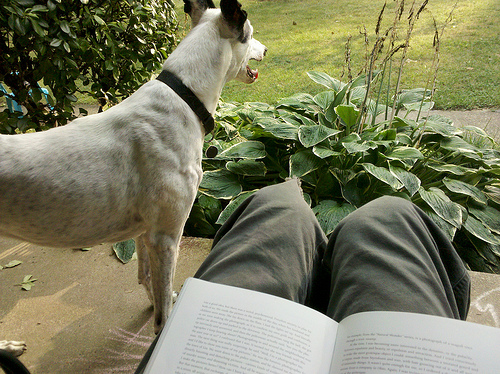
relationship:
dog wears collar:
[0, 0, 273, 325] [154, 71, 223, 131]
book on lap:
[133, 270, 497, 371] [195, 180, 455, 304]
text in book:
[204, 307, 309, 359] [133, 270, 497, 371]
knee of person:
[245, 169, 307, 220] [132, 176, 469, 373]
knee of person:
[341, 190, 427, 238] [132, 176, 469, 373]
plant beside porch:
[288, 88, 488, 231] [467, 264, 498, 322]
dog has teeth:
[0, 0, 273, 325] [248, 65, 261, 73]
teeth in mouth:
[248, 65, 261, 73] [242, 71, 262, 80]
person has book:
[132, 176, 469, 373] [133, 270, 497, 371]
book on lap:
[133, 270, 497, 371] [222, 184, 441, 313]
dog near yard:
[0, 0, 273, 325] [256, 8, 494, 105]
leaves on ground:
[7, 254, 34, 290] [47, 246, 138, 364]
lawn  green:
[0, 3, 499, 116] [451, 50, 477, 72]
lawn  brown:
[0, 3, 499, 116] [450, 24, 470, 35]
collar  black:
[154, 65, 216, 135] [188, 98, 202, 110]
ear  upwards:
[217, 0, 254, 39] [174, 2, 262, 43]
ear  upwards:
[182, 0, 217, 28] [174, 2, 262, 43]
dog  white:
[0, 0, 273, 325] [74, 137, 103, 150]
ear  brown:
[219, 0, 248, 27] [228, 11, 239, 25]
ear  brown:
[174, 1, 216, 29] [228, 11, 239, 25]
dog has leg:
[0, 0, 273, 325] [134, 231, 178, 301]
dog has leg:
[0, 0, 273, 325] [140, 172, 199, 336]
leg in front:
[134, 231, 178, 301] [115, 152, 198, 350]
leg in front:
[140, 172, 199, 336] [115, 152, 198, 350]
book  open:
[144, 276, 497, 373] [122, 261, 496, 368]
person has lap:
[132, 176, 469, 373] [202, 164, 472, 325]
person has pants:
[194, 165, 480, 320] [194, 161, 479, 322]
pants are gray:
[194, 161, 479, 322] [374, 254, 404, 288]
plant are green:
[190, 70, 500, 271] [446, 144, 461, 147]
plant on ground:
[190, 70, 500, 271] [150, 69, 499, 241]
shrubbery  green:
[0, 0, 181, 149] [97, 29, 117, 48]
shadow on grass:
[277, 29, 337, 74] [180, 10, 498, 117]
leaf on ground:
[12, 272, 41, 293] [1, 234, 229, 367]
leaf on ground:
[2, 251, 24, 270] [1, 234, 229, 367]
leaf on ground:
[69, 245, 95, 255] [1, 234, 229, 367]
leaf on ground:
[107, 240, 145, 275] [1, 234, 229, 367]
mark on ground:
[472, 287, 498, 323] [462, 259, 498, 321]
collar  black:
[153, 69, 218, 144] [200, 111, 212, 128]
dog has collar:
[0, 0, 267, 336] [153, 69, 218, 144]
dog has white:
[0, 0, 273, 325] [90, 128, 110, 145]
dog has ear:
[0, 0, 267, 336] [219, 0, 248, 27]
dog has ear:
[0, 0, 267, 336] [182, 0, 217, 28]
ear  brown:
[219, 0, 248, 27] [222, 16, 234, 26]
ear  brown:
[182, 0, 217, 28] [222, 16, 234, 26]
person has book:
[194, 165, 480, 320] [129, 254, 499, 372]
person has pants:
[132, 176, 469, 373] [126, 180, 468, 372]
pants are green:
[126, 180, 468, 372] [252, 200, 292, 244]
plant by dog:
[190, 70, 500, 271] [0, 0, 273, 325]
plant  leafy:
[190, 70, 500, 271] [408, 122, 476, 181]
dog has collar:
[0, 0, 273, 325] [153, 69, 218, 144]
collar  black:
[153, 69, 218, 144] [183, 93, 205, 108]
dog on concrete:
[0, 0, 273, 325] [3, 207, 495, 372]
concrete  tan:
[3, 200, 208, 370] [25, 312, 49, 333]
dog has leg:
[0, 0, 273, 325] [138, 176, 182, 338]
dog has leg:
[0, 0, 273, 325] [129, 228, 159, 304]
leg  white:
[138, 176, 182, 338] [154, 210, 169, 227]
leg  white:
[129, 228, 159, 304] [154, 210, 169, 227]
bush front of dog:
[0, 1, 208, 156] [0, 0, 273, 325]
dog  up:
[0, 0, 273, 325] [0, 5, 271, 326]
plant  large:
[190, 70, 500, 271] [192, 61, 498, 245]